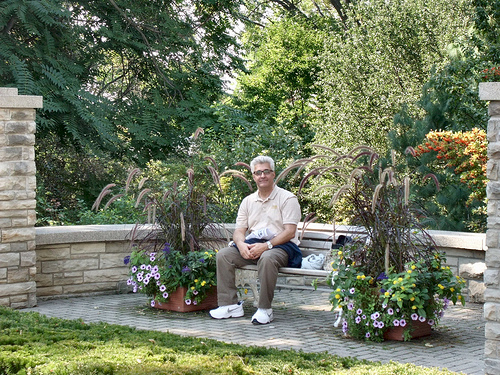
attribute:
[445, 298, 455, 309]
flower — yellow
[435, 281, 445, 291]
flower — yellow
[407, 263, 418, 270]
flower — yellow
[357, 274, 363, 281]
flower — yellow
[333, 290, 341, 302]
flower — yellow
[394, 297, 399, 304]
leaf — green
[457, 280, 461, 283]
leaf — green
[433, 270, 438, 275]
leaf — green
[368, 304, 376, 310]
leaf — green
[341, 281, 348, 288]
leaf — green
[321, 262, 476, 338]
flowers — pot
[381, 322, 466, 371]
brick — paved, ground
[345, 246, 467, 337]
leaves — green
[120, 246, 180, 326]
flowers — purple